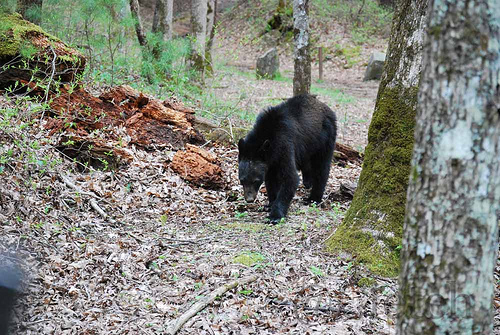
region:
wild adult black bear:
[236, 91, 339, 226]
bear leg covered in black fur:
[310, 157, 328, 202]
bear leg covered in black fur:
[275, 166, 295, 225]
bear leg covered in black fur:
[302, 167, 312, 189]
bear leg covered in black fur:
[263, 176, 277, 208]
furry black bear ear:
[260, 135, 271, 157]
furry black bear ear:
[236, 138, 246, 155]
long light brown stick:
[171, 269, 264, 334]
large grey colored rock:
[256, 48, 283, 78]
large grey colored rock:
[360, 48, 389, 83]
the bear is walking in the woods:
[228, 92, 345, 224]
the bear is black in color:
[226, 87, 347, 223]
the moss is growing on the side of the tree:
[326, 81, 426, 275]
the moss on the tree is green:
[326, 79, 422, 289]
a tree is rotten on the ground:
[69, 81, 211, 152]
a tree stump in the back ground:
[251, 50, 281, 82]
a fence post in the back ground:
[315, 45, 328, 79]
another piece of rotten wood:
[168, 143, 225, 187]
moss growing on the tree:
[1, 12, 80, 65]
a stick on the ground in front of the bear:
[153, 275, 265, 333]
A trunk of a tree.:
[398, 3, 497, 334]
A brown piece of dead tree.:
[165, 138, 225, 185]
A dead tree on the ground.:
[0, 5, 227, 191]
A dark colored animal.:
[233, 93, 336, 221]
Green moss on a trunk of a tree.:
[323, 71, 418, 275]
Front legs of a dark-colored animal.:
[266, 174, 300, 223]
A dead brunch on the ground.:
[163, 272, 258, 331]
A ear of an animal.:
[236, 135, 246, 151]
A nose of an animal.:
[246, 194, 255, 202]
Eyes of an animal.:
[237, 175, 262, 184]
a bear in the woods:
[91, 37, 408, 267]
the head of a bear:
[233, 159, 266, 202]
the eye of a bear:
[253, 175, 262, 184]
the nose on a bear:
[244, 195, 256, 204]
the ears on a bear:
[234, 138, 271, 155]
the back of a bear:
[258, 80, 329, 135]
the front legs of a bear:
[265, 174, 305, 222]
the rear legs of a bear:
[301, 164, 334, 202]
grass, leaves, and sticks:
[81, 191, 236, 333]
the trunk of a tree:
[401, 32, 493, 324]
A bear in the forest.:
[219, 70, 374, 218]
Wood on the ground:
[73, 74, 218, 169]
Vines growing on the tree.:
[381, 76, 422, 281]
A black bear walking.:
[213, 80, 348, 221]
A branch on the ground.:
[150, 274, 288, 310]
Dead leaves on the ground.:
[75, 223, 186, 307]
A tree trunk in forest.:
[237, 31, 292, 83]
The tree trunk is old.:
[432, 27, 488, 322]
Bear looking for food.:
[208, 76, 353, 224]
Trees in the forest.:
[106, 25, 188, 86]